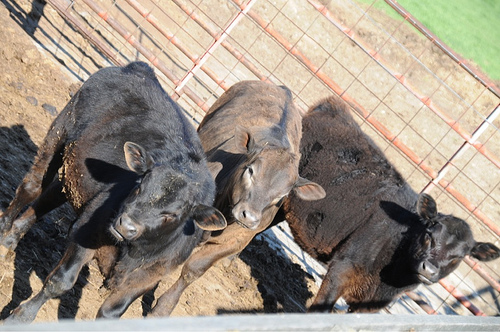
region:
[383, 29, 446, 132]
metal fence dirt behind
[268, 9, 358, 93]
metal fence dirt behind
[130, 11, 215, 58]
metal fence dirt behind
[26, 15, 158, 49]
metal fence dirt behind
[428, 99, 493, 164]
metal fence dirt behind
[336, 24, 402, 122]
metal fence dirt behind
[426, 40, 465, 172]
metal fence dirt behind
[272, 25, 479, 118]
metal fence dirt behind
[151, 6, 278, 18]
metal fence dirt behind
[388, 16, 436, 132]
metal fence dirt behind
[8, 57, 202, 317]
COW IN PADDOCK AREA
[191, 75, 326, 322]
COW IN PADDOCK AREA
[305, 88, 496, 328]
COW IN PADDOCK AREA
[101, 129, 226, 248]
HEAD OF STANDING COW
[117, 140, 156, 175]
EAR OF STANDING COW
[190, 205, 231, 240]
EAR OF STANDING COW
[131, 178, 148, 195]
EYE OF STANDING COW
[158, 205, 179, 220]
EYE OF STANDING COW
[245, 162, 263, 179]
EYE OF STANDING COW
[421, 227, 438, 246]
EYE OF STANDING COW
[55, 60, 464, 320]
cattle are behind fence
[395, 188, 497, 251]
calf has black ears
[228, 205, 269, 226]
calf has brown nose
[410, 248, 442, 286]
calf has dark brown nose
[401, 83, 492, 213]
white posts behind calves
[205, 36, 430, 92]
brown ground outside fence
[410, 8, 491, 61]
green grass outside fence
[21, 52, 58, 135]
brown dirt in pen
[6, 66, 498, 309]
three cows in a caged in area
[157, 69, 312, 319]
a smaller brown cow between two black cows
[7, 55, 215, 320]
this black cow is dirty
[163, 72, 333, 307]
dirt all over the middle cow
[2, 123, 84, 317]
reflection of the cow on the ground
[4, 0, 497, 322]
fence around the cow area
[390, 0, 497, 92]
green grass on the ground behind the cage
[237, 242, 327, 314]
cow shadow on the dirt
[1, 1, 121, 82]
shadow of the fence on the dirt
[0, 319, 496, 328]
rail of the fence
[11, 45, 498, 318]
cows in the fenced area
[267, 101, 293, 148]
black stripe on the cow's back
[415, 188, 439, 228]
ear of the black cow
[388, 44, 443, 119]
fence enclosure behind the cows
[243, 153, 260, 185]
eye of the brown cow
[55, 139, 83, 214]
mud on the cow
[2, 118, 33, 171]
shadow of the cow on the ground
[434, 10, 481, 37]
grass in front of the fence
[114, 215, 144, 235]
nose on the cow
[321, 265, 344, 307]
leg of the cow